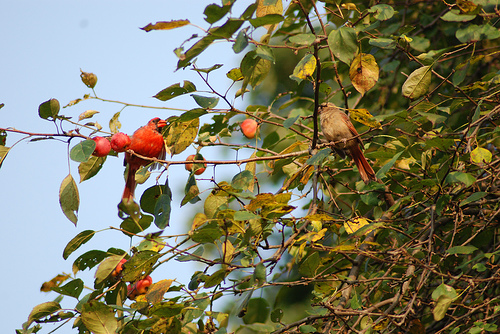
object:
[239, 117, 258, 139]
apple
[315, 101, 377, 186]
bird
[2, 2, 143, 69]
sky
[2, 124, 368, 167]
branch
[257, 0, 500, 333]
tree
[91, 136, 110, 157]
apple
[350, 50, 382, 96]
leaf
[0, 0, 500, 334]
photo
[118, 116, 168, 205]
bird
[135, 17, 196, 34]
leaves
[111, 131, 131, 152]
fruit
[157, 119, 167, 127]
beak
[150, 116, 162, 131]
face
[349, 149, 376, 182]
tail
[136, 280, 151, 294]
berry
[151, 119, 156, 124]
eyes